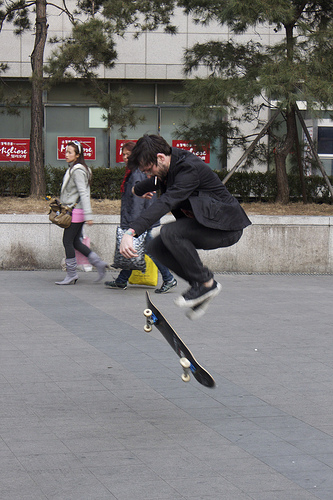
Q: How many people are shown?
A: Three.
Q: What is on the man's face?
A: Glasses.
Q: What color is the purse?
A: Brown.